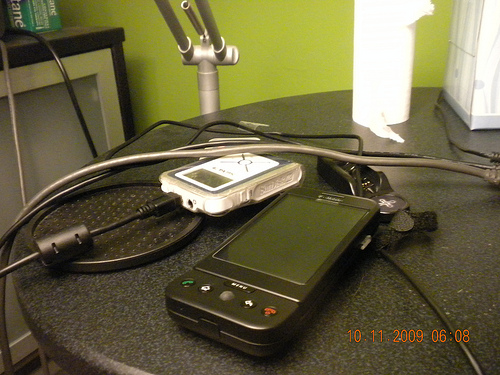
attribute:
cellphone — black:
[177, 160, 377, 360]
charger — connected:
[48, 188, 268, 318]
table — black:
[409, 202, 492, 322]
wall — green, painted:
[110, 118, 460, 340]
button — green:
[175, 273, 197, 289]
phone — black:
[164, 180, 387, 360]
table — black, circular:
[11, 83, 483, 368]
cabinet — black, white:
[7, 24, 122, 369]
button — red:
[258, 297, 276, 315]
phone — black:
[150, 188, 385, 360]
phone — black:
[160, 182, 398, 368]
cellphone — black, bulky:
[157, 185, 386, 363]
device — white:
[155, 145, 303, 218]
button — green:
[175, 270, 195, 295]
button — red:
[257, 302, 280, 318]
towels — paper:
[344, 2, 428, 144]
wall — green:
[56, 0, 451, 133]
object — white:
[158, 147, 304, 212]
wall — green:
[63, 1, 452, 157]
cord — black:
[3, 192, 181, 273]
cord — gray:
[6, 140, 484, 226]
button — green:
[176, 273, 200, 293]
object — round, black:
[25, 175, 206, 273]